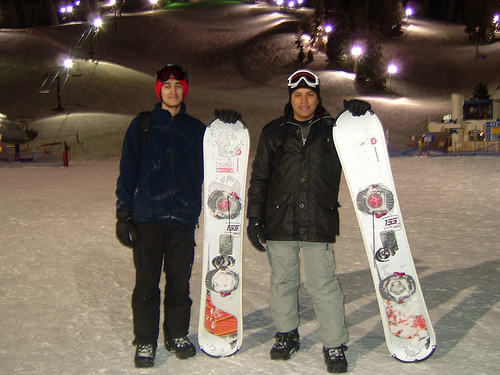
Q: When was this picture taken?
A: At night.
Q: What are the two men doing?
A: Snowboarding.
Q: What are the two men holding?
A: Snowboards.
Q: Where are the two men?
A: In the snow.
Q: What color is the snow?
A: White.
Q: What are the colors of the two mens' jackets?
A: Blue and black.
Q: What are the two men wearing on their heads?
A: Beanies and ski goggles.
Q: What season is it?
A: Winter.